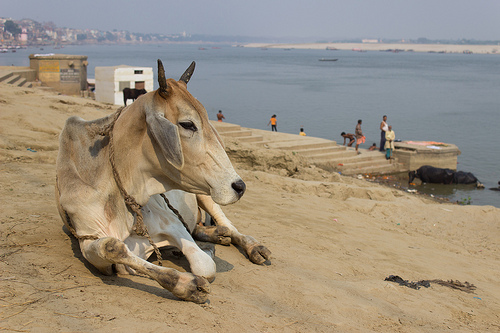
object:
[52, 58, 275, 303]
animal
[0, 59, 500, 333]
sand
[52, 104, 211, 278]
rope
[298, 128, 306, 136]
people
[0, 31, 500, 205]
water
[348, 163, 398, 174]
steps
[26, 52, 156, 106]
group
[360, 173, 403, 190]
garbage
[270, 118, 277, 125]
shirt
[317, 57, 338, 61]
boat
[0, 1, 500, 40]
sky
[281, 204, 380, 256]
dirt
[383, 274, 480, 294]
plant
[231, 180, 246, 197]
nose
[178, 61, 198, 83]
horns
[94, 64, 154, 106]
structure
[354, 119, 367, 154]
person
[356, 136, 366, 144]
orange shorts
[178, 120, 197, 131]
eyes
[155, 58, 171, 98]
ears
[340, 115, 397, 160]
group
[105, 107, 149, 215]
neck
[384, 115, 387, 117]
hair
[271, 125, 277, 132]
pants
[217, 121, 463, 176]
dock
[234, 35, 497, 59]
object